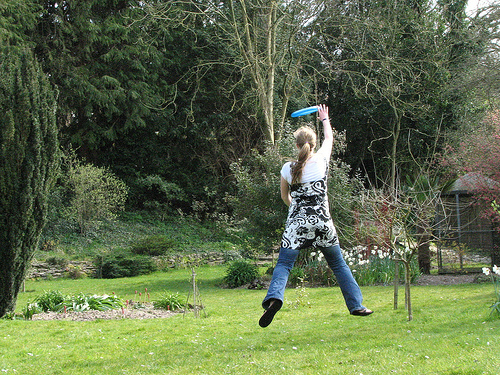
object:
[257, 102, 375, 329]
person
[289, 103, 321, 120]
frisbee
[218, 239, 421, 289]
patch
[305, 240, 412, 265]
flowers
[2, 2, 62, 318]
tree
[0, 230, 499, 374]
garden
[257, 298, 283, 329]
left foot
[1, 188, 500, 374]
field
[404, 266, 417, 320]
trunk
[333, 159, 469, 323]
trees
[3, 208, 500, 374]
grass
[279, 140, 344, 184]
shirt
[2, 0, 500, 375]
air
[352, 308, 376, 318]
sandal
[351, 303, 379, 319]
foot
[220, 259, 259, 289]
bush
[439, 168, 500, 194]
roof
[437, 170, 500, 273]
gazebo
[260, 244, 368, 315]
jeans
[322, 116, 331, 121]
accessory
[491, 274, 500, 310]
stems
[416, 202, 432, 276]
beam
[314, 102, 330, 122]
hand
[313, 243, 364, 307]
legs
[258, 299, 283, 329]
sole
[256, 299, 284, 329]
sandal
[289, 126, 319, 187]
hair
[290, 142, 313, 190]
ponytail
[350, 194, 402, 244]
no leaves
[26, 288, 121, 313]
plants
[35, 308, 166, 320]
mulch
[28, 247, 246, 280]
rock wall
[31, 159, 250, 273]
hill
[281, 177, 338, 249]
design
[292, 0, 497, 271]
trees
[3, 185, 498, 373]
ground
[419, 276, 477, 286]
rocks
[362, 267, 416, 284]
leaves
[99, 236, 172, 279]
bushes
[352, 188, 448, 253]
branches